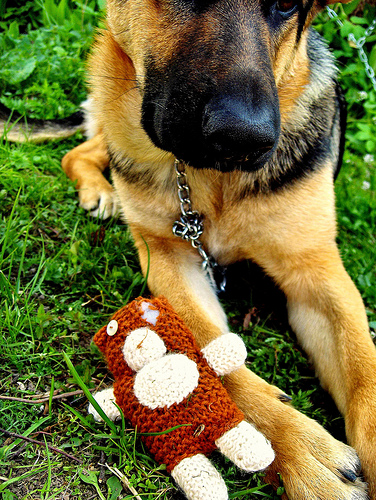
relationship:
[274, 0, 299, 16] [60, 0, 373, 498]
eye of dog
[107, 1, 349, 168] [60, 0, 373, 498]
face on dog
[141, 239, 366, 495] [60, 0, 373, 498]
leg on dog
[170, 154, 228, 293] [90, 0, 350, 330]
chain on dog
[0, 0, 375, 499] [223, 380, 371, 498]
dog has paw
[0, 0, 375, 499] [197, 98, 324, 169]
dog has nose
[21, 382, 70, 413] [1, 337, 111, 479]
stick on grass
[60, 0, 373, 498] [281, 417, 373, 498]
dog has paw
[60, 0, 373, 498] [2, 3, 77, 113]
dog on grass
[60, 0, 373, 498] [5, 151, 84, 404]
dog on grass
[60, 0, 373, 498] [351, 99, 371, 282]
dog on grass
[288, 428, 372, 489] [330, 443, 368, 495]
paw has toenail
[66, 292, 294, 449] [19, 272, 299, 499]
doll on ground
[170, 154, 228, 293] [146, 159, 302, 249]
chain on chest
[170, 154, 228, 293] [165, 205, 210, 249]
chain has knot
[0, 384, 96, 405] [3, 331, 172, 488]
stick on ground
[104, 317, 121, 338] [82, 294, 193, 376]
button on doll face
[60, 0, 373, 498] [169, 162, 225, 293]
dog has chain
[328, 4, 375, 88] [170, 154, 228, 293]
chain connected to chain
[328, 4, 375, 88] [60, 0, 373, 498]
chain connected to dog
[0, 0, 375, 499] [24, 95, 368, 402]
dog sitting in yard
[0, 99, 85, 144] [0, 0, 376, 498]
dog tail lying of yard